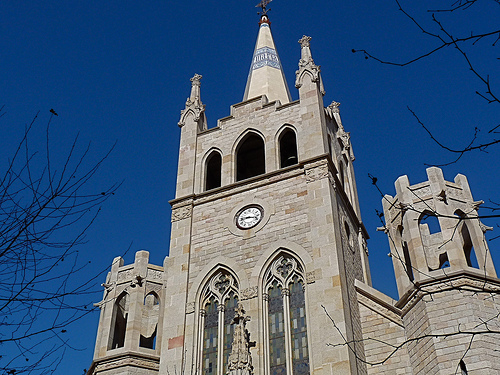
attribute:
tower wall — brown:
[263, 192, 333, 254]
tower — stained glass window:
[223, 3, 297, 109]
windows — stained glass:
[193, 240, 318, 372]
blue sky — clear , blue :
[6, 0, 497, 360]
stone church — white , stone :
[93, 3, 495, 373]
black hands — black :
[237, 215, 258, 217]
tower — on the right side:
[380, 165, 500, 369]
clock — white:
[231, 203, 266, 232]